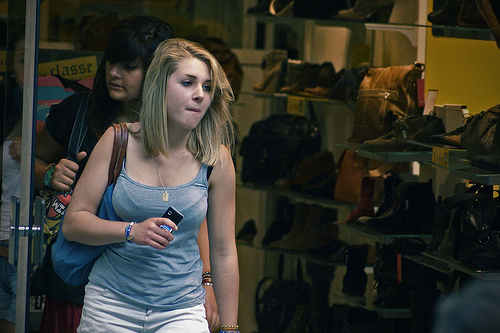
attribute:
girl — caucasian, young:
[60, 33, 251, 332]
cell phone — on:
[153, 205, 183, 239]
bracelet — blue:
[123, 218, 138, 244]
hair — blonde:
[132, 34, 242, 176]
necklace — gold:
[146, 136, 190, 204]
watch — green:
[39, 162, 56, 191]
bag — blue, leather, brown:
[43, 114, 127, 296]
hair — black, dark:
[83, 17, 175, 127]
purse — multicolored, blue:
[50, 69, 101, 181]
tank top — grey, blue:
[88, 137, 210, 313]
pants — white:
[73, 276, 218, 332]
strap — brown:
[108, 116, 132, 187]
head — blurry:
[431, 264, 498, 332]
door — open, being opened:
[0, 3, 42, 331]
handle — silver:
[6, 192, 47, 270]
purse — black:
[232, 104, 323, 196]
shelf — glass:
[210, 162, 363, 213]